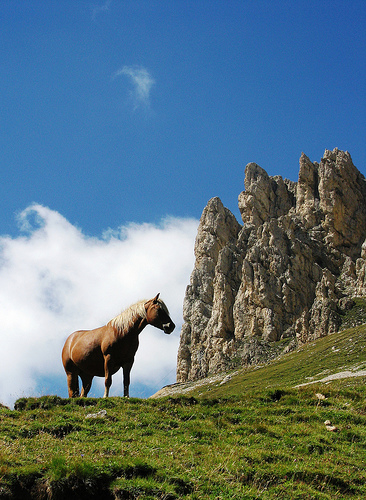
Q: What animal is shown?
A: Horse.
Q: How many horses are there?
A: One.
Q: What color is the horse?
A: Tan.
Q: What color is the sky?
A: Blue.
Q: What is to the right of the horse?
A: Rocks.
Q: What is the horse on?
A: Grass.